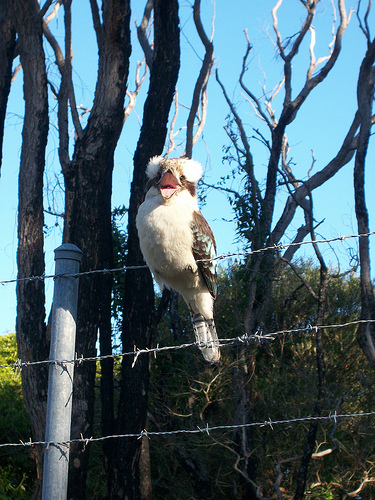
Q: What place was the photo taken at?
A: It was taken at the forest.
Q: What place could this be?
A: It is a forest.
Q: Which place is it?
A: It is a forest.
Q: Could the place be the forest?
A: Yes, it is the forest.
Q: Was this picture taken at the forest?
A: Yes, it was taken in the forest.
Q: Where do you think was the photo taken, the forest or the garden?
A: It was taken at the forest.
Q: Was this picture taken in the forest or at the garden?
A: It was taken at the forest.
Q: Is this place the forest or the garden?
A: It is the forest.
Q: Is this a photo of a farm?
A: No, the picture is showing a forest.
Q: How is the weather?
A: It is cloudless.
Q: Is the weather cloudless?
A: Yes, it is cloudless.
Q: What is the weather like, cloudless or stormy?
A: It is cloudless.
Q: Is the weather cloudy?
A: No, it is cloudless.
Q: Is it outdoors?
A: Yes, it is outdoors.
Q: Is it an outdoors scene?
A: Yes, it is outdoors.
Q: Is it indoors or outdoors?
A: It is outdoors.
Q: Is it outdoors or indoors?
A: It is outdoors.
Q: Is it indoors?
A: No, it is outdoors.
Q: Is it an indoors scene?
A: No, it is outdoors.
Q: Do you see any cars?
A: No, there are no cars.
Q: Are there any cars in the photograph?
A: No, there are no cars.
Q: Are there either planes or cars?
A: No, there are no cars or planes.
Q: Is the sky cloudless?
A: Yes, the sky is cloudless.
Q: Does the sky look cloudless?
A: Yes, the sky is cloudless.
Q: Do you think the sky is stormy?
A: No, the sky is cloudless.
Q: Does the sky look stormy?
A: No, the sky is cloudless.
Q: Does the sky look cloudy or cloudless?
A: The sky is cloudless.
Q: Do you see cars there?
A: No, there are no cars.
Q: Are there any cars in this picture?
A: No, there are no cars.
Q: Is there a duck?
A: No, there are no ducks.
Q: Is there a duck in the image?
A: No, there are no ducks.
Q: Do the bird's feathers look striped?
A: Yes, the feathers are striped.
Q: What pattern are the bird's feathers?
A: The feathers are striped.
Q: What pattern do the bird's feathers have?
A: The feathers have striped pattern.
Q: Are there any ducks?
A: No, there are no ducks.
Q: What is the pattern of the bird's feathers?
A: The feathers are striped.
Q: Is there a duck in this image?
A: No, there are no ducks.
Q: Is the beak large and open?
A: Yes, the beak is large and open.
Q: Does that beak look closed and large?
A: No, the beak is large but open.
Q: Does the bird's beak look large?
A: Yes, the beak is large.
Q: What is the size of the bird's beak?
A: The beak is large.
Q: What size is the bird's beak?
A: The beak is large.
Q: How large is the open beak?
A: The beak is large.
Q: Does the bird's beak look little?
A: No, the beak is large.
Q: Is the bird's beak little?
A: No, the beak is large.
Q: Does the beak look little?
A: No, the beak is large.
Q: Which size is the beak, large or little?
A: The beak is large.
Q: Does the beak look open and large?
A: Yes, the beak is open and large.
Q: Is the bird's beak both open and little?
A: No, the beak is open but large.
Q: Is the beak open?
A: Yes, the beak is open.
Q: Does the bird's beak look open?
A: Yes, the beak is open.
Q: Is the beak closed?
A: No, the beak is open.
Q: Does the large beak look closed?
A: No, the beak is open.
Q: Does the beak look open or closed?
A: The beak is open.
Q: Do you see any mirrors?
A: No, there are no mirrors.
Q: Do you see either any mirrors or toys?
A: No, there are no mirrors or toys.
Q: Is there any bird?
A: Yes, there is a bird.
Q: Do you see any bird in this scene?
A: Yes, there is a bird.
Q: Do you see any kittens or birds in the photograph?
A: Yes, there is a bird.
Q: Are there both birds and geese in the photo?
A: No, there is a bird but no geese.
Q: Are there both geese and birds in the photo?
A: No, there is a bird but no geese.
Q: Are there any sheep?
A: No, there are no sheep.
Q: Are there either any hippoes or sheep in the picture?
A: No, there are no sheep or hippoes.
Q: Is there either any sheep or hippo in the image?
A: No, there are no sheep or hippoes.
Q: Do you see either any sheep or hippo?
A: No, there are no sheep or hippoes.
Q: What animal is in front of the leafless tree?
A: The bird is in front of the tree.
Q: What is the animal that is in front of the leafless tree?
A: The animal is a bird.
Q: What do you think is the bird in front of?
A: The bird is in front of the tree.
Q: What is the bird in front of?
A: The bird is in front of the tree.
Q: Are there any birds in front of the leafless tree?
A: Yes, there is a bird in front of the tree.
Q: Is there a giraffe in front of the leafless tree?
A: No, there is a bird in front of the tree.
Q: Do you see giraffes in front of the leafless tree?
A: No, there is a bird in front of the tree.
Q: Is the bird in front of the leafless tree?
A: Yes, the bird is in front of the tree.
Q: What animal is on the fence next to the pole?
A: The bird is on the fence.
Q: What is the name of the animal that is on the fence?
A: The animal is a bird.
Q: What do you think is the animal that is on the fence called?
A: The animal is a bird.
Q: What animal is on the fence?
A: The animal is a bird.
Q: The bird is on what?
A: The bird is on the fence.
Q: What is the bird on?
A: The bird is on the fence.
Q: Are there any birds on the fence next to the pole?
A: Yes, there is a bird on the fence.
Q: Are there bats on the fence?
A: No, there is a bird on the fence.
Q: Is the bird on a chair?
A: No, the bird is on the fence.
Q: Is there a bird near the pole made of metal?
A: Yes, there is a bird near the pole.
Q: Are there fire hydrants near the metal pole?
A: No, there is a bird near the pole.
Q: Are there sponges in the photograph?
A: No, there are no sponges.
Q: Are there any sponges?
A: No, there are no sponges.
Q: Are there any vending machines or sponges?
A: No, there are no sponges or vending machines.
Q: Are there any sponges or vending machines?
A: No, there are no sponges or vending machines.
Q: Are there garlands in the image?
A: No, there are no garlands.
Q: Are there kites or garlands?
A: No, there are no garlands or kites.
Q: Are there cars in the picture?
A: No, there are no cars.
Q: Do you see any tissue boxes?
A: No, there are no tissue boxes.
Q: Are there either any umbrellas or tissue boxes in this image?
A: No, there are no tissue boxes or umbrellas.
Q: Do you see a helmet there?
A: No, there are no helmets.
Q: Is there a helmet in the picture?
A: No, there are no helmets.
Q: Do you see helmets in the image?
A: No, there are no helmets.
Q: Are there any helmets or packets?
A: No, there are no helmets or packets.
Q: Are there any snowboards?
A: No, there are no snowboards.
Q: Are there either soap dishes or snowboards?
A: No, there are no snowboards or soap dishes.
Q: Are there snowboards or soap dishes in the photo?
A: No, there are no snowboards or soap dishes.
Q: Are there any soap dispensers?
A: No, there are no soap dispensers.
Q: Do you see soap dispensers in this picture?
A: No, there are no soap dispensers.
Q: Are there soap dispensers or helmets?
A: No, there are no soap dispensers or helmets.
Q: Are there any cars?
A: No, there are no cars.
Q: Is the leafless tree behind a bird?
A: Yes, the tree is behind a bird.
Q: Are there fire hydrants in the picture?
A: No, there are no fire hydrants.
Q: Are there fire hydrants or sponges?
A: No, there are no fire hydrants or sponges.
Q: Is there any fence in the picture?
A: Yes, there is a fence.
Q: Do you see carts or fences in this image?
A: Yes, there is a fence.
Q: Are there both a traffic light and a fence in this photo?
A: No, there is a fence but no traffic lights.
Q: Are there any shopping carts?
A: No, there are no shopping carts.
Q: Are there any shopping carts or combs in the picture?
A: No, there are no shopping carts or combs.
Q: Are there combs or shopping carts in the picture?
A: No, there are no shopping carts or combs.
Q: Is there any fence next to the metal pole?
A: Yes, there is a fence next to the pole.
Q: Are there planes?
A: No, there are no planes.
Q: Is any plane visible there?
A: No, there are no airplanes.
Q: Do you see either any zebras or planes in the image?
A: No, there are no planes or zebras.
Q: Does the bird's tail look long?
A: Yes, the tail is long.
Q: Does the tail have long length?
A: Yes, the tail is long.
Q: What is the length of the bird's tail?
A: The tail is long.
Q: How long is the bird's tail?
A: The tail is long.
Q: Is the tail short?
A: No, the tail is long.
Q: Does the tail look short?
A: No, the tail is long.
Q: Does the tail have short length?
A: No, the tail is long.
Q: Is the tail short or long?
A: The tail is long.